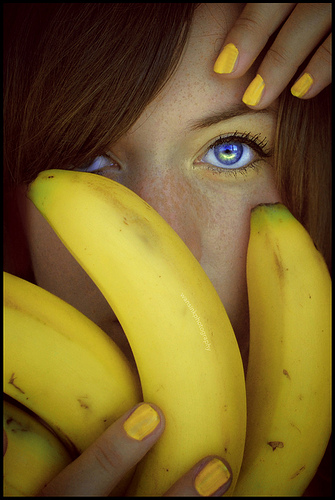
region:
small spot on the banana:
[266, 430, 291, 460]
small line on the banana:
[286, 456, 311, 481]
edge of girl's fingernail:
[142, 397, 165, 423]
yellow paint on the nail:
[122, 402, 164, 446]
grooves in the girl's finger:
[86, 432, 129, 474]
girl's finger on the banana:
[74, 369, 249, 481]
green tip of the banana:
[19, 154, 83, 202]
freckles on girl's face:
[145, 105, 196, 136]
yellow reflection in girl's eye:
[187, 130, 274, 178]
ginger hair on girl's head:
[47, 27, 178, 120]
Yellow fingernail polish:
[208, 33, 319, 109]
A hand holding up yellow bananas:
[25, 322, 317, 487]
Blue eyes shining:
[206, 131, 256, 177]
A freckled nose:
[134, 162, 214, 215]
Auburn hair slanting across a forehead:
[14, 3, 199, 167]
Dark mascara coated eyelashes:
[206, 123, 276, 163]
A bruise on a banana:
[4, 416, 64, 445]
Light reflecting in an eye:
[207, 130, 245, 169]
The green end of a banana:
[247, 198, 297, 227]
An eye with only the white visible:
[84, 142, 139, 176]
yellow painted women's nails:
[206, 54, 332, 106]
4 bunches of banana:
[39, 182, 295, 492]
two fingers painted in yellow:
[114, 379, 230, 494]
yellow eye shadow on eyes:
[170, 93, 299, 191]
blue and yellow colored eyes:
[213, 145, 253, 170]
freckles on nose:
[162, 171, 251, 252]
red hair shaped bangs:
[31, 3, 171, 131]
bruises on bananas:
[7, 365, 59, 430]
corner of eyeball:
[85, 143, 131, 181]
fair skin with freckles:
[163, 103, 192, 177]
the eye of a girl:
[189, 126, 278, 174]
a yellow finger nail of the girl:
[121, 399, 163, 443]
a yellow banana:
[20, 168, 250, 498]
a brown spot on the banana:
[265, 432, 287, 453]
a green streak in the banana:
[3, 408, 60, 464]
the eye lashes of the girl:
[197, 126, 278, 158]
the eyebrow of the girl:
[185, 100, 278, 135]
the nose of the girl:
[122, 163, 206, 273]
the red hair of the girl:
[0, 1, 202, 188]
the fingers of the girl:
[212, 0, 333, 129]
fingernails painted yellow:
[243, 72, 319, 107]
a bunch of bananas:
[0, 260, 306, 494]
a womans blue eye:
[195, 132, 266, 172]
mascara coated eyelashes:
[207, 125, 269, 147]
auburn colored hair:
[1, 12, 169, 171]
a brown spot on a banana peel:
[266, 432, 289, 455]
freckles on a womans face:
[142, 171, 224, 236]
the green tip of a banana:
[242, 198, 297, 226]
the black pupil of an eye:
[222, 146, 235, 157]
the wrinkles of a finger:
[266, 40, 295, 67]